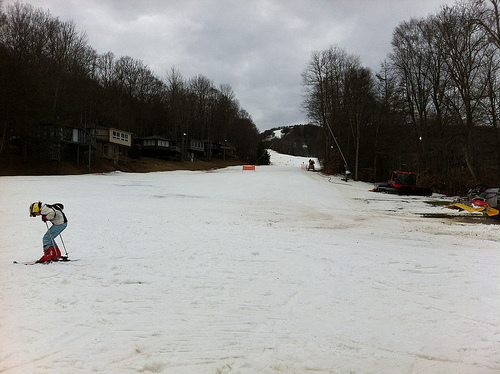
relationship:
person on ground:
[18, 193, 82, 270] [248, 166, 324, 250]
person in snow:
[18, 193, 82, 270] [323, 227, 407, 310]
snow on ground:
[323, 227, 407, 310] [248, 166, 324, 250]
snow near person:
[323, 227, 407, 310] [18, 193, 82, 270]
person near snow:
[18, 193, 82, 270] [323, 227, 407, 310]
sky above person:
[177, 5, 304, 75] [18, 193, 82, 270]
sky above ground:
[177, 5, 304, 75] [248, 166, 324, 250]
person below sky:
[18, 193, 82, 270] [177, 5, 304, 75]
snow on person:
[323, 227, 407, 310] [18, 193, 82, 270]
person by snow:
[18, 193, 82, 270] [323, 227, 407, 310]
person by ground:
[18, 193, 82, 270] [248, 166, 324, 250]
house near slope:
[78, 115, 133, 172] [8, 142, 355, 271]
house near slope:
[143, 116, 191, 171] [8, 142, 355, 271]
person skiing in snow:
[28, 200, 68, 263] [9, 161, 484, 371]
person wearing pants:
[28, 200, 68, 263] [37, 218, 68, 254]